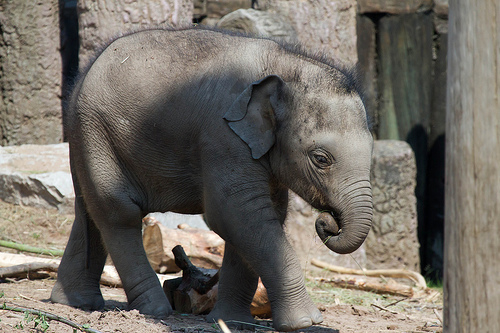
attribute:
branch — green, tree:
[0, 234, 66, 260]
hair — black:
[89, 7, 371, 114]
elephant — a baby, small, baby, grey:
[47, 25, 375, 332]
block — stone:
[278, 141, 451, 307]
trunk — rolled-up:
[316, 180, 386, 264]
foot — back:
[119, 269, 173, 317]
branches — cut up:
[160, 240, 222, 315]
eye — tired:
[315, 150, 328, 167]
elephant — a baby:
[33, 23, 436, 318]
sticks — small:
[306, 257, 446, 330]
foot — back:
[115, 279, 175, 316]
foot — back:
[48, 265, 106, 309]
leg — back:
[72, 120, 172, 317]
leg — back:
[49, 140, 108, 307]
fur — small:
[260, 42, 376, 122]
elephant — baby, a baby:
[17, 17, 397, 327]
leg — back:
[65, 159, 198, 319]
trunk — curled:
[313, 175, 374, 255]